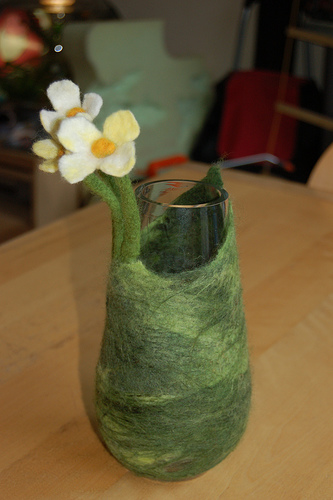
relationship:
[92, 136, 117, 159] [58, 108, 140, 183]
pistil on fake flower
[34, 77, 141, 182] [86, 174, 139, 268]
fake flower on stem